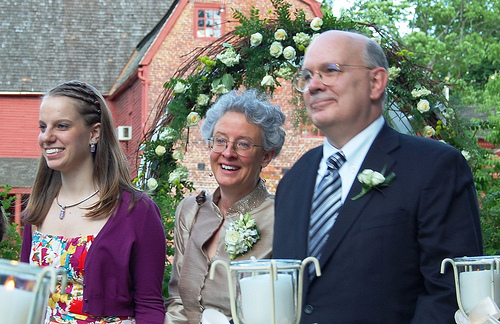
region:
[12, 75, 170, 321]
The girl is smiling.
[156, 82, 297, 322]
The woman is smiling.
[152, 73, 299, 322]
The woman is wearing glasses.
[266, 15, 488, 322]
The man is smiling.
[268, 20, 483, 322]
The man is wearing glasses.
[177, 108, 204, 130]
The flower is white.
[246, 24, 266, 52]
The flower is white.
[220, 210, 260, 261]
The corsage is white.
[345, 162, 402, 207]
The boutonniere is white.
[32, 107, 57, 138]
eye of a person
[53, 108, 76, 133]
eye of a person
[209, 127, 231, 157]
eye of a person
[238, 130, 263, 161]
eye of a person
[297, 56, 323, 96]
eye of a person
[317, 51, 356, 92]
eye of a person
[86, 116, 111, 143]
ear of a person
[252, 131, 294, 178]
ear of a person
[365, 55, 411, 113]
ear of a person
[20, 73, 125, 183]
head of a person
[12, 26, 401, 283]
this is a celebration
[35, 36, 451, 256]
this is at a wedding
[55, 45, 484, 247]
this is a ceremony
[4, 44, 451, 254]
there are three people here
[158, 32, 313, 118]
this is an arch way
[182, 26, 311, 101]
the arch has flowers and wicker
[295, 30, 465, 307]
this is an old man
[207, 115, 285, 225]
this is an old woman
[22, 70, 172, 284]
this is a young woman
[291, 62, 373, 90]
glasses on a man's face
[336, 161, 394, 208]
a flower on a man's suit jacket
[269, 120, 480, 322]
a suit jacket on a man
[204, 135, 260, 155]
glasses on a woman's face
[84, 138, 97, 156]
an earring in a woman's ear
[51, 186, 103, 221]
a necklace on a woman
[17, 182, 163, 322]
a purple sweater on a woman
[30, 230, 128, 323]
a brightly colored dress on a woman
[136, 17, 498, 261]
a rose wreath behind people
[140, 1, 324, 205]
a red brick end wall on a building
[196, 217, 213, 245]
edge of a coat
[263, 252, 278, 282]
part of a handle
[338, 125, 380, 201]
part of a flower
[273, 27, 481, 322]
the man is wearing a suit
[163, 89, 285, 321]
the elderly woman is wearing a corsage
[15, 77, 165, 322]
the young woman is wearing a purple jacket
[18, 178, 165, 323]
the short jacket is purple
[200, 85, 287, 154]
the hair is gray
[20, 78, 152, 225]
the hair is brown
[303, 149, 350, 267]
a gray striped tie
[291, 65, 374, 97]
a man's eyeglasses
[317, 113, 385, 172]
a man's white shirt collar